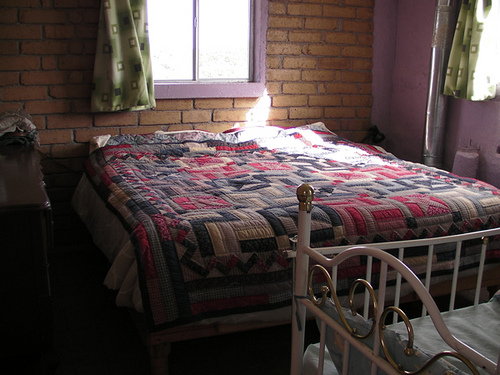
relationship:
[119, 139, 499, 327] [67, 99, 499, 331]
quilt on bed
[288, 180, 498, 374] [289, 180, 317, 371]
bed has post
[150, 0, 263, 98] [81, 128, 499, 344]
window above bed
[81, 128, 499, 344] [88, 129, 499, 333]
bed has quilt